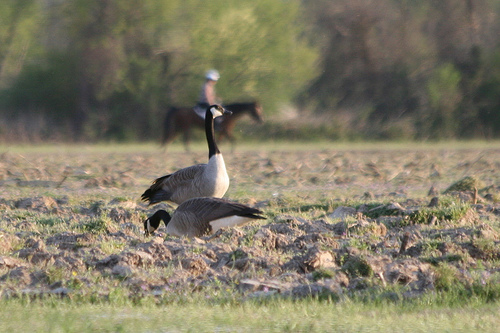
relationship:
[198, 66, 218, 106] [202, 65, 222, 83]
man wearing helmet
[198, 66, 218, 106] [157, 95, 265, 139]
man on horse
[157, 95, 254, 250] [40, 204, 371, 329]
goose on grass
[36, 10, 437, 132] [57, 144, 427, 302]
trees behind grass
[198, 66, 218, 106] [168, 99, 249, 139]
man on horse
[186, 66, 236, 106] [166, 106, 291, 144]
man on horse